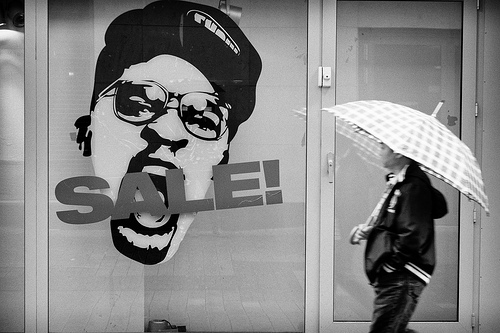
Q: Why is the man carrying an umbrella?
A: It's raining.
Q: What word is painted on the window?
A: Sale.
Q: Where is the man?
A: In front of a store.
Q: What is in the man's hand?
A: An umbrella.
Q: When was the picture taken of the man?
A: Daytime.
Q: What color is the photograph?
A: Black and white.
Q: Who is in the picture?
A: A man.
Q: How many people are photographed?
A: One.